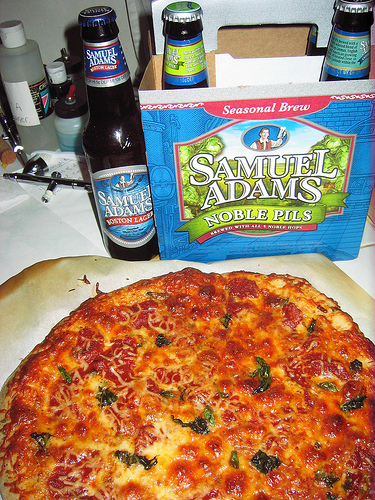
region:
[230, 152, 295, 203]
part of some graphics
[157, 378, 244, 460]
surface of a pizza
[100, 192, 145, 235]
part of a bottle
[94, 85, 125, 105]
neck of a bottle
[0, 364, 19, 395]
edge of a pizza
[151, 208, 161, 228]
edge of the box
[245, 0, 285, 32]
surface of the box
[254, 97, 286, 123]
red part of the box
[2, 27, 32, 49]
part of a top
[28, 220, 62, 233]
part of a desktop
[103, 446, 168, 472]
piece of green basil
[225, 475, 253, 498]
small burnt crust on pizza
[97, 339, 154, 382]
curvy lines in pizza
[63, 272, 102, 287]
small pieces of crust on white paper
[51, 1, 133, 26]
blue bottle top of beer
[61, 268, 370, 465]
large pizza in box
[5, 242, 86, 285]
edge of brown cutting board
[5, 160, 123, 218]
large silver wine opener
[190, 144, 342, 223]
white words on beer container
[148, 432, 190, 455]
gooey cheese on pizza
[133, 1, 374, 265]
Box of beer has only two bottles.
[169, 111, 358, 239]
Beer is "Samuel Adams"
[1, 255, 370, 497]
Cooked pizza in front of beer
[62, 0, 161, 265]
Bottle of beer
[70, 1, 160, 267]
Beer has a lid on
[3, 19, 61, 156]
Bottle with white cap.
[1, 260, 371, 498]
Pizza has cheese and green vegetables.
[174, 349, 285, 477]
Green vegetables on pizza.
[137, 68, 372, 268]
Box of beer is blue and green.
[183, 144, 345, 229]
Letters of box are white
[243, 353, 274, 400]
fresh basil atop pizza margherita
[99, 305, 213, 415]
cheese melted into curvy stripes on tomato sauce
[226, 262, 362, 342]
a bit of sauceless homeemade crust, right top corner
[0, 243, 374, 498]
pizza placed on parchment with one burnt edge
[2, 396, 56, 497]
black+white pepper grains atop pizza lower left corner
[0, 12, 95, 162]
crafting supplies upper left corner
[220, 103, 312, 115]
Seasonal Brew in white on red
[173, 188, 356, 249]
NOBLE PILS across a chartreuse printed ribbon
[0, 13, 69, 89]
two white snap-top caps on two crafting bottles of something[s]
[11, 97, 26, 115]
A in hand printing on taller bottle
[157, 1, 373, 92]
two beers in a box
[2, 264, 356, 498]
pizza on a box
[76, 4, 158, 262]
beer bottle next to box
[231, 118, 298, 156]
picture on box holding a beer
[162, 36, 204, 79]
Yellow sticker on bottle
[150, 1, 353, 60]
handle of beer box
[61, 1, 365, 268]
three beer bottles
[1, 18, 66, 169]
opaque bottle with white lid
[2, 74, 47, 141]
white sticker on bottle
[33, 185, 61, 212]
white tape over piece of metal